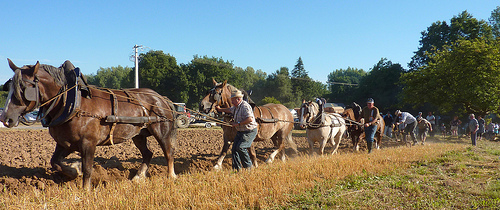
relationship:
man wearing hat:
[215, 90, 259, 173] [229, 90, 246, 100]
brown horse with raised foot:
[0, 57, 182, 192] [48, 142, 77, 181]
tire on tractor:
[174, 112, 190, 127] [171, 102, 191, 127]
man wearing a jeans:
[215, 90, 259, 173] [230, 129, 257, 170]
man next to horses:
[222, 77, 267, 175] [17, 54, 188, 183]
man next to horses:
[222, 77, 267, 175] [204, 71, 300, 170]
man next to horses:
[222, 77, 267, 175] [292, 93, 367, 165]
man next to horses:
[222, 77, 267, 175] [349, 94, 449, 151]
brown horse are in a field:
[0, 57, 182, 192] [6, 115, 493, 208]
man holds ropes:
[215, 90, 259, 173] [93, 79, 250, 134]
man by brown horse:
[215, 90, 259, 173] [0, 57, 182, 192]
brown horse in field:
[0, 57, 182, 192] [1, 127, 498, 208]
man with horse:
[215, 90, 259, 173] [37, 54, 215, 209]